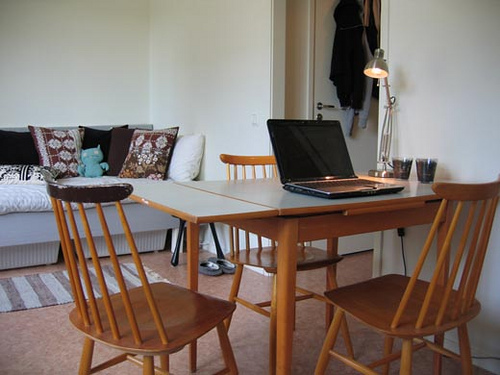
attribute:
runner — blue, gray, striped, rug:
[0, 262, 172, 314]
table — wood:
[127, 173, 454, 374]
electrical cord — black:
[398, 227, 407, 277]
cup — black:
[415, 158, 438, 183]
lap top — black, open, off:
[267, 119, 405, 198]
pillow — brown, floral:
[118, 151, 172, 180]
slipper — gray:
[197, 255, 235, 275]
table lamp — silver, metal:
[363, 49, 396, 177]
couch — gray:
[1, 123, 205, 270]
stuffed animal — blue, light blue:
[77, 144, 109, 177]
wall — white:
[148, 0, 273, 278]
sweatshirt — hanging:
[329, 2, 366, 110]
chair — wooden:
[312, 173, 499, 374]